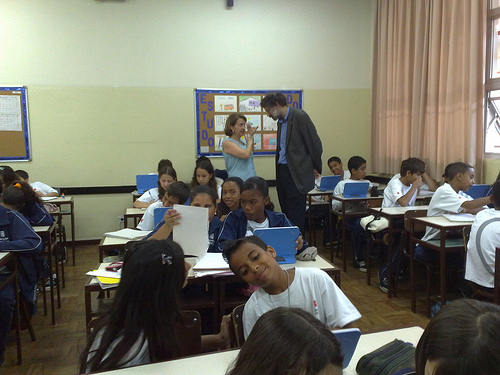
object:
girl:
[141, 184, 223, 257]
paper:
[170, 201, 211, 257]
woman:
[219, 112, 258, 184]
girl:
[140, 185, 224, 265]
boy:
[218, 234, 360, 342]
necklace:
[266, 270, 290, 309]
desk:
[406, 214, 496, 320]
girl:
[214, 175, 304, 255]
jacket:
[212, 210, 310, 257]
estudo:
[194, 94, 214, 156]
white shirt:
[413, 181, 478, 249]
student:
[71, 237, 233, 374]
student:
[408, 160, 496, 317]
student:
[331, 155, 378, 274]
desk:
[327, 191, 385, 275]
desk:
[82, 250, 344, 343]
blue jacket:
[214, 209, 308, 254]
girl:
[213, 176, 250, 224]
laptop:
[340, 182, 370, 199]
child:
[376, 156, 438, 294]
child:
[130, 165, 183, 209]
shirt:
[240, 265, 363, 341]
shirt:
[135, 186, 168, 209]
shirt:
[380, 171, 431, 209]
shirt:
[414, 181, 490, 246]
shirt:
[330, 177, 375, 211]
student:
[135, 180, 194, 238]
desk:
[96, 228, 228, 266]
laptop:
[315, 174, 343, 191]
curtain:
[370, 3, 488, 185]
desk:
[368, 204, 431, 299]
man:
[258, 91, 324, 240]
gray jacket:
[270, 106, 323, 196]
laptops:
[133, 173, 160, 194]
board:
[194, 89, 303, 157]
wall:
[0, 0, 375, 249]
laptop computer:
[250, 224, 301, 265]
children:
[77, 238, 197, 374]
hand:
[240, 130, 256, 143]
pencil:
[145, 187, 155, 205]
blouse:
[220, 136, 257, 183]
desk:
[80, 324, 426, 374]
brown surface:
[195, 91, 215, 154]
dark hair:
[73, 237, 195, 374]